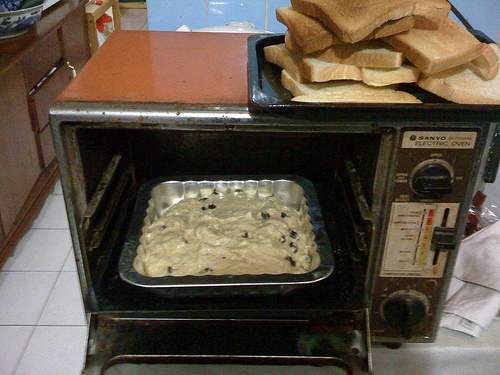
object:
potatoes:
[150, 186, 308, 283]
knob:
[412, 163, 458, 202]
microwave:
[53, 28, 500, 375]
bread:
[415, 39, 500, 105]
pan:
[247, 31, 498, 110]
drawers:
[0, 8, 90, 256]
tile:
[16, 325, 92, 375]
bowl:
[1, 2, 46, 38]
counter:
[2, 0, 85, 107]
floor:
[0, 182, 500, 375]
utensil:
[465, 193, 485, 239]